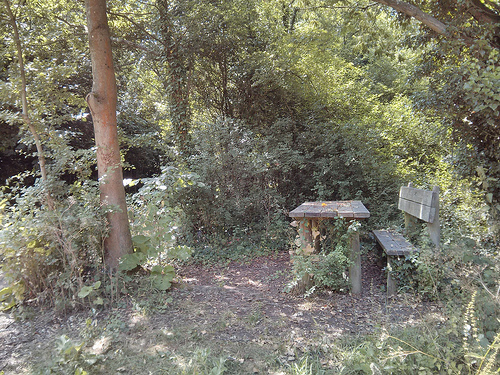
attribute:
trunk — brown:
[93, 184, 146, 282]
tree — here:
[72, 6, 152, 281]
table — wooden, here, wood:
[284, 180, 373, 299]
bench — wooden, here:
[378, 166, 444, 291]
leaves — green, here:
[309, 55, 351, 93]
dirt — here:
[214, 275, 252, 301]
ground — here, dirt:
[65, 283, 413, 365]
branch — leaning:
[374, 1, 447, 55]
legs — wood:
[295, 226, 368, 296]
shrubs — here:
[177, 107, 274, 223]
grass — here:
[346, 334, 390, 369]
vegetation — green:
[341, 39, 460, 145]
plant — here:
[323, 251, 348, 292]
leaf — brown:
[320, 200, 328, 207]